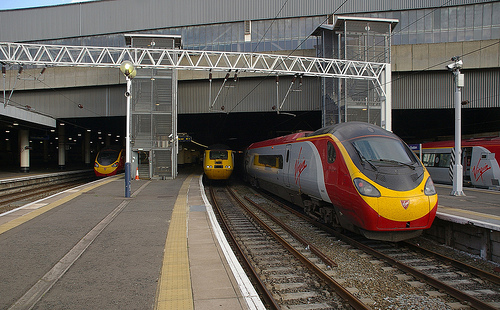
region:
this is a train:
[214, 98, 448, 245]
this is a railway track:
[248, 215, 346, 309]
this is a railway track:
[241, 193, 295, 273]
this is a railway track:
[257, 179, 347, 283]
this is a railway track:
[390, 249, 478, 309]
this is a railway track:
[217, 182, 277, 244]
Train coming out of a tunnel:
[78, 123, 134, 185]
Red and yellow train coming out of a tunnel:
[82, 46, 145, 188]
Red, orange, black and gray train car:
[256, 107, 444, 244]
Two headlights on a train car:
[345, 165, 446, 205]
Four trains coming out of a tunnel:
[82, 111, 495, 242]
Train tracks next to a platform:
[200, 185, 315, 303]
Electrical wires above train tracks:
[22, 35, 422, 105]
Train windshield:
[323, 112, 433, 180]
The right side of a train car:
[256, 135, 331, 200]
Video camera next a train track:
[363, 35, 477, 257]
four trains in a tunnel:
[28, 116, 487, 221]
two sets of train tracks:
[265, 260, 470, 308]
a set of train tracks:
[424, 253, 484, 308]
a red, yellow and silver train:
[281, 141, 438, 236]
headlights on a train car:
[342, 180, 443, 202]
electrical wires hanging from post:
[198, 8, 432, 120]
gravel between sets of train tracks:
[332, 265, 427, 308]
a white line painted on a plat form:
[205, 160, 245, 308]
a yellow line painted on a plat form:
[162, 166, 192, 308]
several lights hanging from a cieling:
[44, 123, 114, 162]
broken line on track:
[306, 244, 342, 271]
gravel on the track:
[360, 269, 408, 294]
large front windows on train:
[348, 129, 428, 189]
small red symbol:
[399, 198, 416, 215]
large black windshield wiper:
[351, 134, 431, 184]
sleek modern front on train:
[317, 112, 421, 225]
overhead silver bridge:
[32, 36, 405, 86]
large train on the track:
[276, 100, 451, 241]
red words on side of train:
[288, 141, 325, 181]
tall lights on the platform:
[111, 54, 137, 78]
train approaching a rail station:
[235, 98, 461, 278]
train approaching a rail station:
[198, 125, 245, 214]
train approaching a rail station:
[93, 130, 135, 187]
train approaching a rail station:
[468, 133, 490, 161]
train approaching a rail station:
[79, 133, 124, 192]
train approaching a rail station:
[422, 140, 497, 181]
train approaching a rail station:
[191, 129, 438, 240]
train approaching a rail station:
[71, 135, 162, 212]